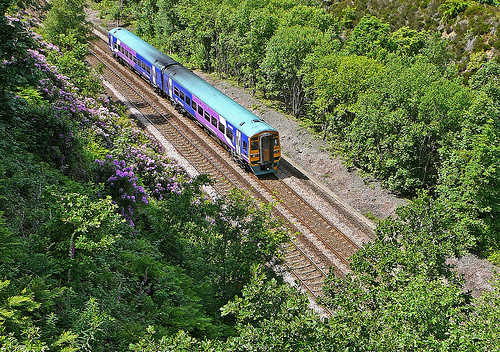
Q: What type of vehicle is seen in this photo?
A: Train.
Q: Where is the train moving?
A: On track.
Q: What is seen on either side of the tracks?
A: Trees.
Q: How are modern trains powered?
A: By engine.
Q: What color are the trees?
A: Green.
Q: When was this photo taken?
A: Daytime.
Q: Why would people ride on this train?
A: To travel.